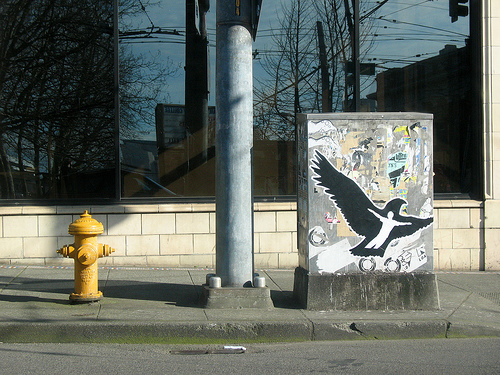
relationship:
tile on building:
[140, 212, 177, 234] [6, 3, 498, 275]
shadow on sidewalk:
[0, 273, 298, 308] [43, 265, 347, 354]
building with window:
[377, 41, 485, 222] [4, 13, 487, 198]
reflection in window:
[0, 0, 482, 203] [120, 0, 496, 203]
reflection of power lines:
[0, 0, 482, 203] [117, 0, 494, 70]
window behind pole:
[4, 13, 487, 198] [208, 2, 270, 292]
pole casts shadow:
[216, 0, 253, 287] [0, 275, 303, 308]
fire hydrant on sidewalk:
[54, 206, 116, 304] [1, 265, 498, 325]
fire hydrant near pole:
[54, 208, 116, 304] [213, 0, 252, 286]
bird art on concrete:
[308, 147, 434, 258] [2, 261, 499, 373]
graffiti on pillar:
[308, 121, 430, 272] [290, 107, 437, 306]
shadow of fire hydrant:
[4, 292, 76, 309] [54, 206, 116, 304]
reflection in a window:
[129, 79, 191, 168] [4, 13, 487, 198]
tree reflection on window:
[8, 0, 113, 193] [0, 0, 112, 197]